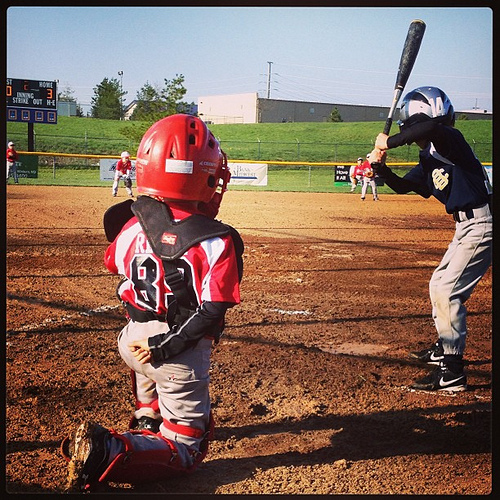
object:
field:
[5, 174, 496, 498]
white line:
[274, 308, 309, 315]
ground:
[6, 176, 491, 494]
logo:
[432, 168, 450, 191]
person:
[6, 141, 19, 184]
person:
[351, 157, 364, 192]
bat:
[370, 19, 426, 170]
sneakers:
[411, 359, 467, 392]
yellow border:
[16, 150, 493, 165]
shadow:
[215, 401, 493, 486]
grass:
[248, 125, 286, 136]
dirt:
[267, 256, 392, 390]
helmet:
[135, 113, 231, 219]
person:
[360, 153, 379, 201]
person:
[112, 151, 134, 197]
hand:
[128, 338, 155, 364]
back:
[123, 216, 211, 315]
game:
[8, 16, 492, 492]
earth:
[6, 184, 492, 495]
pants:
[107, 320, 214, 469]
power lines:
[277, 67, 494, 100]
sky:
[7, 5, 493, 116]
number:
[130, 254, 160, 312]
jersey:
[104, 201, 240, 340]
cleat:
[65, 419, 109, 495]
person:
[368, 85, 495, 392]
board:
[5, 78, 57, 124]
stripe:
[169, 414, 204, 427]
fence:
[7, 151, 495, 188]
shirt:
[375, 120, 493, 213]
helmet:
[396, 86, 455, 145]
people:
[61, 113, 241, 495]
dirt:
[8, 342, 93, 411]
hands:
[369, 148, 387, 165]